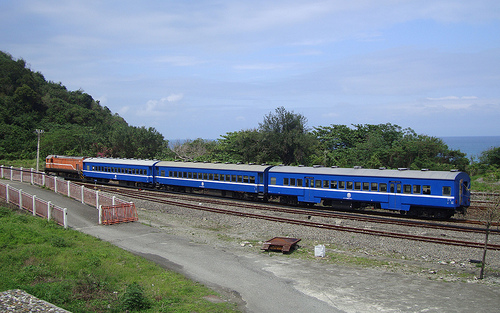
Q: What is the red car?
A: Locomotive.